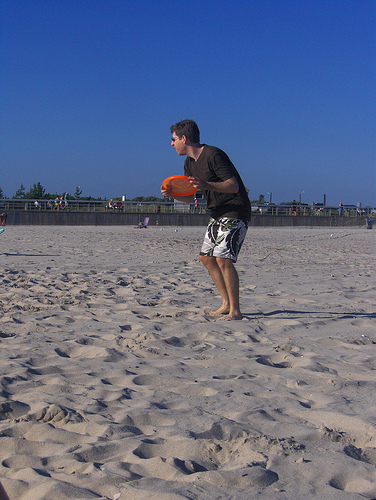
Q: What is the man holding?
A: A Frisbee.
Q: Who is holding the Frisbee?
A: The man.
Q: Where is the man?
A: On the beach.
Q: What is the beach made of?
A: Sand.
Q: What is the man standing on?
A: Sand.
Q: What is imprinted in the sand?
A: Footprints.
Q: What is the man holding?
A: Frisbee.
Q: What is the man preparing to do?
A: Throw the frisbee.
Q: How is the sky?
A: Clear.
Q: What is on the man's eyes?
A: Sunglasses.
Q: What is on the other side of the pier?
A: Trees.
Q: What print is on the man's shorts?
A: Leaves.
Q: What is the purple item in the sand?
A: Chaise lounge.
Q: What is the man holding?
A: Frisbee.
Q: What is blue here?
A: The sky.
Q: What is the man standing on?
A: Sand.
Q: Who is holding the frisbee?
A: The man.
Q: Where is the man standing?
A: A beach.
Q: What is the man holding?
A: A frisbee.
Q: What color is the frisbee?
A: Orange.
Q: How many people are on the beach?
A: 1.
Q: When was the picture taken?
A: Daytime.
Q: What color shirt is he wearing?
A: Black.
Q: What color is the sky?
A: Dark blue.